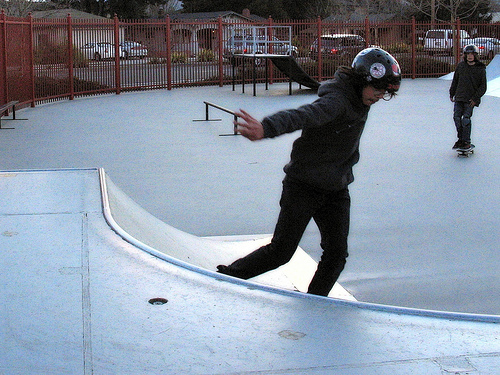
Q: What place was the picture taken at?
A: It was taken at the skate park.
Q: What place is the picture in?
A: It is at the skate park.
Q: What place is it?
A: It is a skate park.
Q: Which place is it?
A: It is a skate park.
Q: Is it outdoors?
A: Yes, it is outdoors.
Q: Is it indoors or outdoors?
A: It is outdoors.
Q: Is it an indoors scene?
A: No, it is outdoors.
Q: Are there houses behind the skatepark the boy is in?
A: Yes, there is a house behind the skate park.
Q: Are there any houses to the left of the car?
A: Yes, there is a house to the left of the car.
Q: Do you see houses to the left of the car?
A: Yes, there is a house to the left of the car.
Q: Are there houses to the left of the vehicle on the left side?
A: Yes, there is a house to the left of the car.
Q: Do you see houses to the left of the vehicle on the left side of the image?
A: Yes, there is a house to the left of the car.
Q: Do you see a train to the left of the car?
A: No, there is a house to the left of the car.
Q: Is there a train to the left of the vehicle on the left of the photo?
A: No, there is a house to the left of the car.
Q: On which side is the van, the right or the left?
A: The van is on the right of the image.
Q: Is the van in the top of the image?
A: Yes, the van is in the top of the image.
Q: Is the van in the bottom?
A: No, the van is in the top of the image.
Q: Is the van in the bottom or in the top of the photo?
A: The van is in the top of the image.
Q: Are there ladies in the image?
A: No, there are no ladies.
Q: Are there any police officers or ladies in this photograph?
A: No, there are no ladies or police officers.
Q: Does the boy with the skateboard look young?
A: Yes, the boy is young.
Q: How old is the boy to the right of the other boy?
A: The boy is young.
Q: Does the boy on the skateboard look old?
A: No, the boy is young.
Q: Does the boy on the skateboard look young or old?
A: The boy is young.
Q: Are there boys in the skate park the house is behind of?
A: Yes, there is a boy in the skate park.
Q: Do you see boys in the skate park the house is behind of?
A: Yes, there is a boy in the skate park.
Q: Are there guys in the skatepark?
A: No, there is a boy in the skatepark.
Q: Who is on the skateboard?
A: The boy is on the skateboard.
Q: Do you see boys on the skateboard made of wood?
A: Yes, there is a boy on the skateboard.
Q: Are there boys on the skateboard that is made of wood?
A: Yes, there is a boy on the skateboard.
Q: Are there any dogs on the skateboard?
A: No, there is a boy on the skateboard.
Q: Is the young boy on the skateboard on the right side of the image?
A: Yes, the boy is on the skateboard.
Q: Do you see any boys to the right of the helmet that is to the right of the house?
A: Yes, there is a boy to the right of the helmet.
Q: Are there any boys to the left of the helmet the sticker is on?
A: No, the boy is to the right of the helmet.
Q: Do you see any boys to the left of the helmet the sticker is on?
A: No, the boy is to the right of the helmet.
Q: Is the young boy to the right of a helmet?
A: Yes, the boy is to the right of a helmet.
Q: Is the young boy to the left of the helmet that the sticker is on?
A: No, the boy is to the right of the helmet.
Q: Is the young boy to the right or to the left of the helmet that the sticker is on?
A: The boy is to the right of the helmet.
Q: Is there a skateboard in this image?
A: Yes, there is a skateboard.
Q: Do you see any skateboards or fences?
A: Yes, there is a skateboard.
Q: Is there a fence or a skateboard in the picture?
A: Yes, there is a skateboard.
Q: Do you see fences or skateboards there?
A: Yes, there is a skateboard.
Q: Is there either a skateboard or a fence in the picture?
A: Yes, there is a skateboard.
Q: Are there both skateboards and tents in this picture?
A: No, there is a skateboard but no tents.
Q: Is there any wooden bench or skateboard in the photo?
A: Yes, there is a wood skateboard.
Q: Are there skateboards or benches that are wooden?
A: Yes, the skateboard is wooden.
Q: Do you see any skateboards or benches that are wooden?
A: Yes, the skateboard is wooden.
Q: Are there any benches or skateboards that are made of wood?
A: Yes, the skateboard is made of wood.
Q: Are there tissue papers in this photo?
A: No, there are no tissue papers.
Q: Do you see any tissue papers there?
A: No, there are no tissue papers.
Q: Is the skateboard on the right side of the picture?
A: Yes, the skateboard is on the right of the image.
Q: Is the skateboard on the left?
A: No, the skateboard is on the right of the image.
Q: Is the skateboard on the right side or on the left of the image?
A: The skateboard is on the right of the image.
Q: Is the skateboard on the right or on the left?
A: The skateboard is on the right of the image.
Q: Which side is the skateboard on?
A: The skateboard is on the right of the image.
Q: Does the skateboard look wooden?
A: Yes, the skateboard is wooden.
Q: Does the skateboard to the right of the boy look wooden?
A: Yes, the skateboard is wooden.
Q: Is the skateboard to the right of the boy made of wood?
A: Yes, the skateboard is made of wood.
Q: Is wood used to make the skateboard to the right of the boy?
A: Yes, the skateboard is made of wood.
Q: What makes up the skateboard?
A: The skateboard is made of wood.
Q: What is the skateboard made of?
A: The skateboard is made of wood.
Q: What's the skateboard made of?
A: The skateboard is made of wood.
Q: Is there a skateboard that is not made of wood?
A: No, there is a skateboard but it is made of wood.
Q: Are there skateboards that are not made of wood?
A: No, there is a skateboard but it is made of wood.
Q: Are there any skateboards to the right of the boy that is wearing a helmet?
A: Yes, there is a skateboard to the right of the boy.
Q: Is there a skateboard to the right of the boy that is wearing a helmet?
A: Yes, there is a skateboard to the right of the boy.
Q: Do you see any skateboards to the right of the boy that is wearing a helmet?
A: Yes, there is a skateboard to the right of the boy.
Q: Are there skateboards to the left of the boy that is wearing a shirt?
A: No, the skateboard is to the right of the boy.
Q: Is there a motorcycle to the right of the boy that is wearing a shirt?
A: No, there is a skateboard to the right of the boy.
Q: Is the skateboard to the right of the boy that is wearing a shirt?
A: Yes, the skateboard is to the right of the boy.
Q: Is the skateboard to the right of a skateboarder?
A: No, the skateboard is to the right of the boy.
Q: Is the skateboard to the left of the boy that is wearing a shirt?
A: No, the skateboard is to the right of the boy.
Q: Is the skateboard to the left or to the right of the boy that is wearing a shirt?
A: The skateboard is to the right of the boy.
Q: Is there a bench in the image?
A: Yes, there is a bench.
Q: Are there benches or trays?
A: Yes, there is a bench.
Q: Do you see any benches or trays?
A: Yes, there is a bench.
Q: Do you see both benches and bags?
A: No, there is a bench but no bags.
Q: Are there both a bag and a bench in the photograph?
A: No, there is a bench but no bags.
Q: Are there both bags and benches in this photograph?
A: No, there is a bench but no bags.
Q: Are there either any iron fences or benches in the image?
A: Yes, there is an iron bench.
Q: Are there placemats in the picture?
A: No, there are no placemats.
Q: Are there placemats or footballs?
A: No, there are no placemats or footballs.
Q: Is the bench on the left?
A: Yes, the bench is on the left of the image.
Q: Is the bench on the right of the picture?
A: No, the bench is on the left of the image.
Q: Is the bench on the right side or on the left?
A: The bench is on the left of the image.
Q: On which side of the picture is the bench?
A: The bench is on the left of the image.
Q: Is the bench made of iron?
A: Yes, the bench is made of iron.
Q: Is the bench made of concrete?
A: No, the bench is made of iron.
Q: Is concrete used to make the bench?
A: No, the bench is made of iron.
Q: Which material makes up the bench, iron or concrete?
A: The bench is made of iron.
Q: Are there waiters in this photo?
A: No, there are no waiters.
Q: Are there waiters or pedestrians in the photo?
A: No, there are no waiters or pedestrians.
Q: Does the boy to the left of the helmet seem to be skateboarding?
A: Yes, the boy is skateboarding.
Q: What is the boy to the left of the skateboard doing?
A: The boy is skateboarding.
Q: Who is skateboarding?
A: The boy is skateboarding.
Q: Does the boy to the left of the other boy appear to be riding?
A: No, the boy is skateboarding.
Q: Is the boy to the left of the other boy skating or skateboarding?
A: The boy is skateboarding.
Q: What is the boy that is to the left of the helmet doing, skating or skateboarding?
A: The boy is skateboarding.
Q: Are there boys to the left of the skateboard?
A: Yes, there is a boy to the left of the skateboard.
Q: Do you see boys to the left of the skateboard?
A: Yes, there is a boy to the left of the skateboard.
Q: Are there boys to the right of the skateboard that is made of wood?
A: No, the boy is to the left of the skateboard.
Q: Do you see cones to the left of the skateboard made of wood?
A: No, there is a boy to the left of the skateboard.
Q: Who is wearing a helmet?
A: The boy is wearing a helmet.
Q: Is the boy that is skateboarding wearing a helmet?
A: Yes, the boy is wearing a helmet.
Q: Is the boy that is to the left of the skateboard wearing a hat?
A: No, the boy is wearing a helmet.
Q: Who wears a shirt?
A: The boy wears a shirt.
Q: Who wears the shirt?
A: The boy wears a shirt.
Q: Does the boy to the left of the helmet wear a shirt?
A: Yes, the boy wears a shirt.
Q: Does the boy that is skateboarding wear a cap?
A: No, the boy wears a shirt.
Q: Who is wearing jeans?
A: The boy is wearing jeans.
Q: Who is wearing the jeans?
A: The boy is wearing jeans.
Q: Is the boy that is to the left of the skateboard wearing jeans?
A: Yes, the boy is wearing jeans.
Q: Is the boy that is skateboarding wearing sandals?
A: No, the boy is wearing jeans.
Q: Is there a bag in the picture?
A: No, there are no bags.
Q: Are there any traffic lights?
A: No, there are no traffic lights.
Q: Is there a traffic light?
A: No, there are no traffic lights.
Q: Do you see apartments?
A: No, there are no apartments.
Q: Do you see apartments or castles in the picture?
A: No, there are no apartments or castles.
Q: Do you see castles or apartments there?
A: No, there are no apartments or castles.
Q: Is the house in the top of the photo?
A: Yes, the house is in the top of the image.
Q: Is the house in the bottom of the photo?
A: No, the house is in the top of the image.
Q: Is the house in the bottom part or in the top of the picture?
A: The house is in the top of the image.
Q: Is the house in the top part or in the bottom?
A: The house is in the top of the image.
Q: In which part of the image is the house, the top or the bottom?
A: The house is in the top of the image.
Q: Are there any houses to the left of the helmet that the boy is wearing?
A: Yes, there is a house to the left of the helmet.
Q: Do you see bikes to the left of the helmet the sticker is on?
A: No, there is a house to the left of the helmet.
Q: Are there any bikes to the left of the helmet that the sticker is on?
A: No, there is a house to the left of the helmet.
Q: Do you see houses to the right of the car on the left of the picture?
A: Yes, there is a house to the right of the car.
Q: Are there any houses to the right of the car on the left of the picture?
A: Yes, there is a house to the right of the car.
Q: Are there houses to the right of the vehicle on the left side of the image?
A: Yes, there is a house to the right of the car.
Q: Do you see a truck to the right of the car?
A: No, there is a house to the right of the car.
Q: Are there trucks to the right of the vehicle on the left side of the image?
A: No, there is a house to the right of the car.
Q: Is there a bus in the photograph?
A: No, there are no buses.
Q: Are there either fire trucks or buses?
A: No, there are no buses or fire trucks.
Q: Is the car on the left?
A: Yes, the car is on the left of the image.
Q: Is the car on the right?
A: No, the car is on the left of the image.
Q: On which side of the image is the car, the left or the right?
A: The car is on the left of the image.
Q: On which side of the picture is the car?
A: The car is on the left of the image.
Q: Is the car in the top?
A: Yes, the car is in the top of the image.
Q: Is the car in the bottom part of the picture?
A: No, the car is in the top of the image.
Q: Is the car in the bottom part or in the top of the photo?
A: The car is in the top of the image.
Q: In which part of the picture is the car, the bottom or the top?
A: The car is in the top of the image.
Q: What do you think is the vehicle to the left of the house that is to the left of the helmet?
A: The vehicle is a car.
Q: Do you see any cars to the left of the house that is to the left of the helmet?
A: Yes, there is a car to the left of the house.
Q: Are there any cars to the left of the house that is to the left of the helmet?
A: Yes, there is a car to the left of the house.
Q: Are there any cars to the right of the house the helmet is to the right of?
A: No, the car is to the left of the house.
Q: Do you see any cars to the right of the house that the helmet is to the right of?
A: No, the car is to the left of the house.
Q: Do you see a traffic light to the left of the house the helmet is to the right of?
A: No, there is a car to the left of the house.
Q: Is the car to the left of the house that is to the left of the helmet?
A: Yes, the car is to the left of the house.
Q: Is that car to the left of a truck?
A: No, the car is to the left of the house.